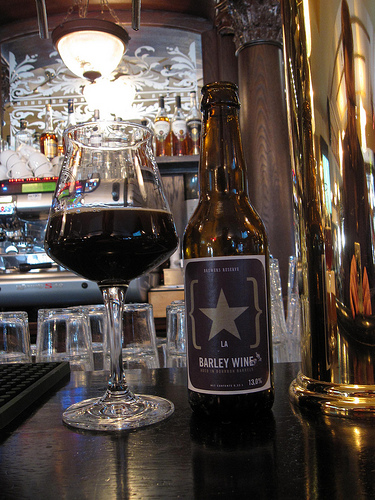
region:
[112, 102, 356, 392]
a bottle of bear on table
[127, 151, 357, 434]
a bottle of wineo n table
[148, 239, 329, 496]
a small bottle of wine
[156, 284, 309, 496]
a small bottle of wine on table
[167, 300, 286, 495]
a tbale with wine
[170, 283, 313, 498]
a table with a bottle of wine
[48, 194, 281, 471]
a wine glass on table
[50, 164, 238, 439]
a glass of wine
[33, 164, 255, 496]
a glass of wine on table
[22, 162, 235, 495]
a table with a glass of wine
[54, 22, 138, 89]
white light over table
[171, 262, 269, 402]
brown and white label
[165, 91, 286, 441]
brown bottle on table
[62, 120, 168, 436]
large clear glass with wine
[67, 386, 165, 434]
round base for glass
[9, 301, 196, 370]
small glasses behind bottle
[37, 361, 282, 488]
glass on black table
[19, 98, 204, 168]
bottles of liquor in rear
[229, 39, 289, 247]
brown pillar behind bottle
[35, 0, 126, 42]
chains holding up light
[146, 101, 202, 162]
bottles of booze sitting on shelf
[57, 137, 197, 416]
a wine glass sitting on a bar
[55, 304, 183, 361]
glasses stacked behind the bar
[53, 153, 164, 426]
a wine glass filled with red wine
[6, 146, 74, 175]
coffee cups stacked behind the bar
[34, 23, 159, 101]
a light shining behing the bar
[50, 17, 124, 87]
a light hanging from the ceiling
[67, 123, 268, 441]
a wine bottle standing next to a wine glass.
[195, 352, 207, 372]
the white letter B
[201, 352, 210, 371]
the white letter A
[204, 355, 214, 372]
the white letter R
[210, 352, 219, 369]
the white letter L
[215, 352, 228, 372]
the white letter E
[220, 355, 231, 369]
the white letter Y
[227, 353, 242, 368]
the white letter W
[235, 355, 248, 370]
the white letter I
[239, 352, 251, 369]
the white letter N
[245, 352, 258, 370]
the capitol letter E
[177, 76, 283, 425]
A bottle on the table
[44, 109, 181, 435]
A glass on the table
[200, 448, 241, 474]
Part of the table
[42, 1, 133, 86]
A light hanging from the ceiling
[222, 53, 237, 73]
Part of the wall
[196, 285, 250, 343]
A star on the bottle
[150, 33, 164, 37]
Part of the mirror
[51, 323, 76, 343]
Part of the glass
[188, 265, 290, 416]
a bottle on the counter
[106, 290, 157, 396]
a glass on the counter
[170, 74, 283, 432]
beer bottle on black bar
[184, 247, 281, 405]
gold star on beer bottle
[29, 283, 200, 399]
liquor glasses behind black bar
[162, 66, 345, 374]
reflection of beer bottle on wall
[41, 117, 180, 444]
glass of beer on black bar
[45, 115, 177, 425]
glass of dark beer on black bar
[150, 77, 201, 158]
liquor bottle on shelf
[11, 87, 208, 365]
liquor bottle on shelf behind bar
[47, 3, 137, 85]
glass globe hanging in front of mirror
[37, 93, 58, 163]
glass of liquor by etched mirror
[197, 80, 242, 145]
Top of a bottle